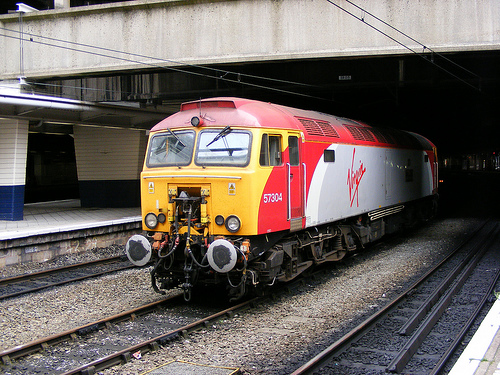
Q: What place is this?
A: It is a tunnel.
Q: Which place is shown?
A: It is a tunnel.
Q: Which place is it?
A: It is a tunnel.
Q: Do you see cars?
A: No, there are no cars.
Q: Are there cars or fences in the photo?
A: No, there are no cars or fences.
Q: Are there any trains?
A: Yes, there is a train.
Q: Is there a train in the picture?
A: Yes, there is a train.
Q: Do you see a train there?
A: Yes, there is a train.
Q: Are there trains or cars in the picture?
A: Yes, there is a train.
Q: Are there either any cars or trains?
A: Yes, there is a train.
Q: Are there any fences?
A: No, there are no fences.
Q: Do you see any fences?
A: No, there are no fences.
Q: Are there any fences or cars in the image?
A: No, there are no fences or cars.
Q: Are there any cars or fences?
A: No, there are no fences or cars.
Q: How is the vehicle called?
A: The vehicle is a train.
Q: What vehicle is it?
A: The vehicle is a train.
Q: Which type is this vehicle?
A: This is a train.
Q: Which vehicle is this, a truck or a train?
A: This is a train.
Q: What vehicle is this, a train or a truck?
A: This is a train.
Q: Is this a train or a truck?
A: This is a train.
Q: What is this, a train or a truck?
A: This is a train.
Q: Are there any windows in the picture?
A: Yes, there are windows.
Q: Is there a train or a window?
A: Yes, there are windows.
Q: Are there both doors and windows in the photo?
A: Yes, there are both windows and doors.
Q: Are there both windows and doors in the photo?
A: Yes, there are both windows and doors.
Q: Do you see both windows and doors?
A: Yes, there are both windows and doors.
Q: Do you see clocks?
A: No, there are no clocks.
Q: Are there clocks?
A: No, there are no clocks.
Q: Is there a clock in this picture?
A: No, there are no clocks.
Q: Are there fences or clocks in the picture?
A: No, there are no clocks or fences.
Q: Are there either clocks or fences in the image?
A: No, there are no clocks or fences.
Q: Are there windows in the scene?
A: Yes, there are windows.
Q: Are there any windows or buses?
A: Yes, there are windows.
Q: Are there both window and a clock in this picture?
A: No, there are windows but no clocks.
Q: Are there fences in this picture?
A: No, there are no fences.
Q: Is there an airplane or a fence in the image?
A: No, there are no fences or airplanes.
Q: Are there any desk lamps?
A: No, there are no desk lamps.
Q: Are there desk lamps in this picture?
A: No, there are no desk lamps.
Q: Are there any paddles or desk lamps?
A: No, there are no desk lamps or paddles.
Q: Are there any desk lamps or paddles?
A: No, there are no desk lamps or paddles.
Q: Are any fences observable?
A: No, there are no fences.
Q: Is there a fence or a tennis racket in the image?
A: No, there are no fences or rackets.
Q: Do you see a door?
A: Yes, there is a door.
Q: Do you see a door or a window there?
A: Yes, there is a door.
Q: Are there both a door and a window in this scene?
A: Yes, there are both a door and a window.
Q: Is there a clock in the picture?
A: No, there are no clocks.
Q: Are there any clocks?
A: No, there are no clocks.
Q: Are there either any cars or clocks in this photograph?
A: No, there are no clocks or cars.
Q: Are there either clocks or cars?
A: No, there are no clocks or cars.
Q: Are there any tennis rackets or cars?
A: No, there are no cars or tennis rackets.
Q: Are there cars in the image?
A: No, there are no cars.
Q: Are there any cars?
A: No, there are no cars.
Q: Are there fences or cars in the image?
A: No, there are no cars or fences.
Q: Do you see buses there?
A: No, there are no buses.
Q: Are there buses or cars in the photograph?
A: No, there are no buses or cars.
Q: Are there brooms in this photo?
A: No, there are no brooms.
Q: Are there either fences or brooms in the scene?
A: No, there are no brooms or fences.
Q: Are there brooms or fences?
A: No, there are no brooms or fences.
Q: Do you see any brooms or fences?
A: No, there are no brooms or fences.